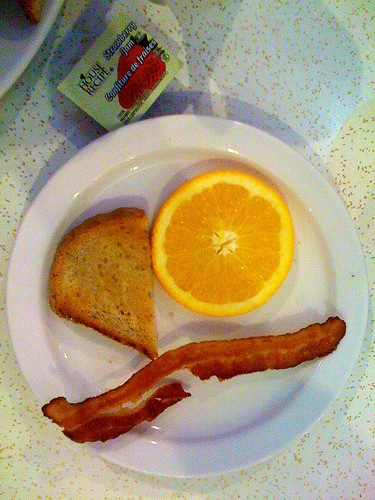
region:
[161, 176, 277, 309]
slice of orange on plate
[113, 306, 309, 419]
one strip of bacon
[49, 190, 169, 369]
half slice of bread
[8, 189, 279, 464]
food on white plate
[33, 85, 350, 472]
white and round plate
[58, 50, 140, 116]
small packet of jam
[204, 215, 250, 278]
yellow core of orange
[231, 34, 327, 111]
white and gold table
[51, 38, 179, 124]
strawberry jam on table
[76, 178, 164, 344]
slice of buttered toast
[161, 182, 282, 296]
this is an orange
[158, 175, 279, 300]
the orange is ripe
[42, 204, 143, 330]
this is a cake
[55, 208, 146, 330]
the cake is big in size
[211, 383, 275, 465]
this is the plate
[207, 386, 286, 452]
the plate is white in color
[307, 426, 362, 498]
this is the table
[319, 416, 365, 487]
the table is tiled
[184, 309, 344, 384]
this is a beef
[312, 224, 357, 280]
the plate is round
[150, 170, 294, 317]
the slice of orange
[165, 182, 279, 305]
the pulps in the orange slice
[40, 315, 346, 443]
the piece of bacon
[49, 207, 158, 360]
the piece of bread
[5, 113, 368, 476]
the round plate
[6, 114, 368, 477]
the white plate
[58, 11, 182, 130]
the small container of jelly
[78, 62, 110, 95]
the words HOUSE RECIPE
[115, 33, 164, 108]
the picture of a strawberry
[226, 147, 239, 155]
the light glare on the plate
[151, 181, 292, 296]
the orange is sliced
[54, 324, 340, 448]
the bacon is half eaten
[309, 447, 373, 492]
the table is ceramic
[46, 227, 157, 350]
the bread is halfcut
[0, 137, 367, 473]
the plate is white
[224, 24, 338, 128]
shadow is on the ground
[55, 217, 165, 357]
the bread is triangle shaped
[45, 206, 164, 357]
the bread is brown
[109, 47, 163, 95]
strawberry is on the box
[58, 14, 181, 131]
the box is square